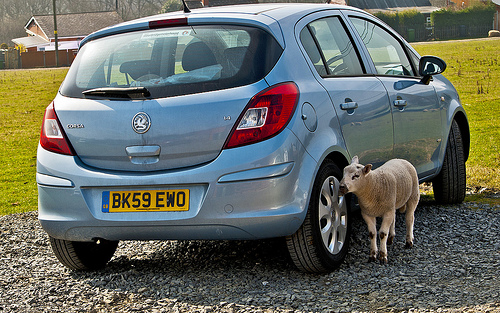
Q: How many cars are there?
A: One.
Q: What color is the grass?
A: Green.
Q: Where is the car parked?
A: On the gravel.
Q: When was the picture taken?
A: In the daytime.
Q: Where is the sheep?
A: Standing by the car.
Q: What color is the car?
A: Blue.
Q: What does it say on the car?
A: BK59EWO.